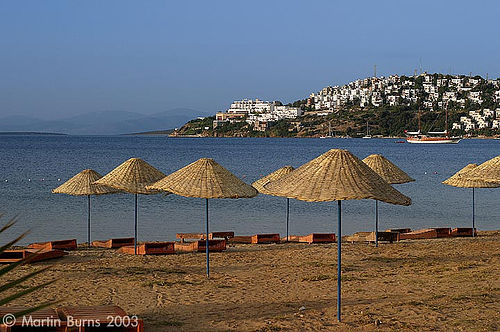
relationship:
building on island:
[227, 97, 301, 121] [165, 72, 500, 138]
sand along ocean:
[1, 227, 500, 332] [1, 136, 500, 250]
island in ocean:
[165, 72, 500, 138] [1, 136, 500, 250]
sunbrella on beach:
[144, 156, 259, 201] [1, 227, 500, 332]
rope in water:
[0, 179, 66, 182] [1, 136, 500, 250]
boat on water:
[404, 103, 463, 144] [1, 136, 500, 250]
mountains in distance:
[1, 105, 221, 135] [1, 100, 219, 136]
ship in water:
[404, 103, 463, 144] [1, 136, 500, 250]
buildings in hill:
[447, 107, 499, 137] [165, 72, 500, 138]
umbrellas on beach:
[50, 156, 257, 199] [1, 227, 500, 332]